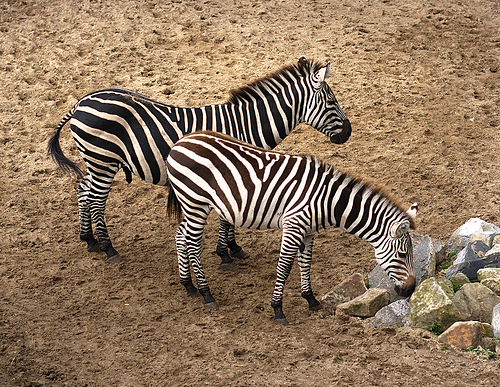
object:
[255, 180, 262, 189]
white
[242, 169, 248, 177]
black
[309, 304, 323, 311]
hoof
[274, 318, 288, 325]
hoof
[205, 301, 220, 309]
hoof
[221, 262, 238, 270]
hoof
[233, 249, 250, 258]
hoof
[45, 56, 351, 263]
zebra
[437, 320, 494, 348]
rock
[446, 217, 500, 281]
rock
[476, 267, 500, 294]
rock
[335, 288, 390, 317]
rock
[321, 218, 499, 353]
pile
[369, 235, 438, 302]
rock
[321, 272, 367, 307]
rock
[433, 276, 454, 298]
moss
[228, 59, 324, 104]
mane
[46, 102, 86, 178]
tail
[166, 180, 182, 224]
tail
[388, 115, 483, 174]
clay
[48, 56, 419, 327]
they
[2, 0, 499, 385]
field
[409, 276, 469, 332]
rock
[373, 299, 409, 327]
rock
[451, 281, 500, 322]
rock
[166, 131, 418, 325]
he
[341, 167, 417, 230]
mane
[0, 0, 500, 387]
dirt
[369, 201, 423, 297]
head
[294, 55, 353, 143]
head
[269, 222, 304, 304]
leg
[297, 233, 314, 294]
leg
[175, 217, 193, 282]
leg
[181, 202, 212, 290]
leg